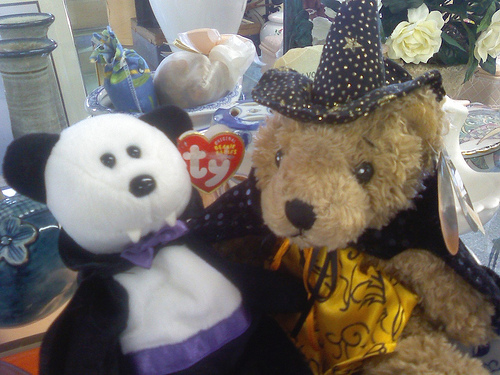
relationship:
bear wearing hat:
[249, 0, 496, 374] [250, 1, 447, 125]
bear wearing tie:
[0, 105, 324, 374] [116, 218, 186, 269]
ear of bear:
[1, 131, 59, 205] [0, 105, 324, 374]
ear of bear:
[139, 103, 191, 143] [0, 105, 324, 374]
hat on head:
[250, 1, 447, 125] [252, 85, 440, 244]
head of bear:
[252, 85, 440, 244] [250, 55, 487, 373]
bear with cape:
[184, 0, 496, 374] [257, 229, 432, 253]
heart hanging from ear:
[174, 131, 247, 194] [139, 103, 191, 143]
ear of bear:
[139, 103, 191, 143] [241, 66, 482, 304]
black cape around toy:
[37, 220, 309, 374] [3, 106, 311, 373]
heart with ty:
[179, 131, 246, 194] [183, 143, 231, 185]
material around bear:
[263, 235, 423, 373] [249, 0, 496, 374]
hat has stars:
[250, 1, 447, 125] [335, 33, 371, 58]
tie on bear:
[118, 218, 200, 268] [0, 105, 324, 374]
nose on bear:
[281, 196, 317, 230] [221, 69, 494, 366]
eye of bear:
[351, 161, 375, 183] [216, 2, 497, 372]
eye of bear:
[98, 151, 123, 172] [21, 133, 206, 264]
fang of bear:
[163, 210, 178, 227] [0, 105, 324, 374]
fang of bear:
[126, 226, 143, 243] [0, 105, 324, 374]